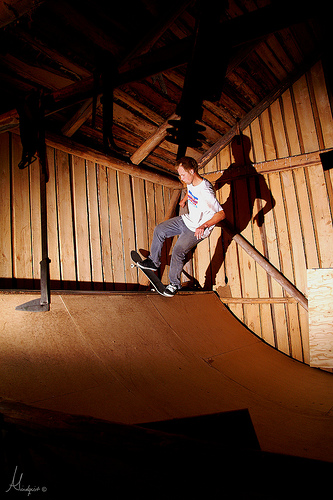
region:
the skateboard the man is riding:
[128, 245, 171, 298]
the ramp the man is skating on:
[2, 288, 332, 453]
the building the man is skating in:
[2, 2, 330, 325]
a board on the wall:
[301, 269, 332, 369]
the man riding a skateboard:
[134, 156, 224, 286]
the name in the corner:
[6, 466, 47, 498]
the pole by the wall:
[27, 110, 62, 312]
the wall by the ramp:
[6, 399, 329, 493]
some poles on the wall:
[221, 225, 297, 313]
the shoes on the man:
[134, 256, 176, 307]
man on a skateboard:
[131, 155, 225, 296]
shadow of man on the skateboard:
[203, 133, 275, 287]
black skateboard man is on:
[129, 247, 175, 298]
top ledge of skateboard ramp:
[65, 289, 154, 293]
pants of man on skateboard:
[150, 215, 198, 285]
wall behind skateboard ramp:
[69, 164, 107, 281]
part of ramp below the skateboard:
[159, 299, 221, 330]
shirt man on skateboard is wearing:
[178, 179, 222, 235]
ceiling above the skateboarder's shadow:
[223, 84, 248, 131]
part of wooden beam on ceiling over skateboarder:
[135, 129, 162, 164]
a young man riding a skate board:
[116, 138, 232, 317]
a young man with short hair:
[161, 146, 210, 193]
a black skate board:
[118, 235, 178, 303]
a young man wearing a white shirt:
[169, 159, 224, 241]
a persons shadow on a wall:
[193, 119, 282, 297]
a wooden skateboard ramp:
[40, 282, 245, 406]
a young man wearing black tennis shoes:
[135, 154, 220, 302]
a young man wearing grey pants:
[152, 151, 205, 289]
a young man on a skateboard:
[113, 147, 230, 320]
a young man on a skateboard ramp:
[121, 146, 244, 396]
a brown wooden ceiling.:
[99, 11, 252, 105]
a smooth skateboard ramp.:
[136, 345, 230, 388]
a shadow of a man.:
[214, 130, 265, 268]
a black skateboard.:
[127, 248, 168, 292]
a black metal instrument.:
[30, 162, 56, 305]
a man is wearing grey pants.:
[147, 215, 187, 252]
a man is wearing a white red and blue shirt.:
[183, 193, 209, 215]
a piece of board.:
[303, 262, 325, 365]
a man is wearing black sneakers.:
[130, 252, 177, 292]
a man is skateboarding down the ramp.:
[117, 145, 236, 356]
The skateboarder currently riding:
[124, 154, 226, 296]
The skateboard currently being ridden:
[127, 249, 172, 300]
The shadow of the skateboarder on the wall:
[139, 131, 277, 292]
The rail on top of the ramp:
[2, 284, 216, 296]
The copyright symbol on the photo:
[39, 481, 49, 495]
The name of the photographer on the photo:
[4, 461, 40, 499]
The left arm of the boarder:
[195, 187, 229, 241]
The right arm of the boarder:
[176, 190, 188, 209]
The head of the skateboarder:
[174, 154, 195, 186]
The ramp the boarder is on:
[2, 286, 332, 497]